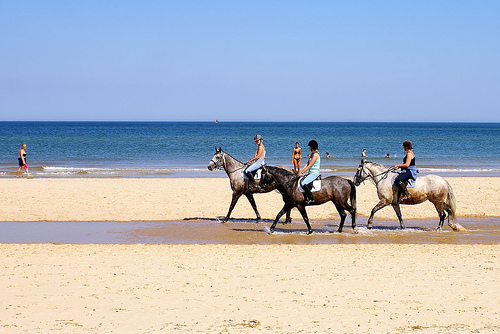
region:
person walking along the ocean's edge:
[16, 141, 29, 178]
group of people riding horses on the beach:
[207, 131, 466, 233]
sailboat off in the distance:
[214, 118, 219, 125]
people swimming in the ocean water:
[322, 148, 392, 158]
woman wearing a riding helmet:
[245, 131, 263, 186]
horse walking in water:
[257, 164, 358, 237]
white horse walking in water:
[351, 155, 462, 235]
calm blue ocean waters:
[55, 121, 186, 166]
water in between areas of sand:
[3, 196, 220, 274]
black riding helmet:
[306, 138, 319, 151]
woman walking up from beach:
[285, 135, 305, 172]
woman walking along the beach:
[4, 131, 44, 185]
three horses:
[214, 128, 497, 246]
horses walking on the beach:
[182, 126, 476, 252]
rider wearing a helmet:
[243, 123, 271, 145]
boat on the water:
[207, 109, 230, 127]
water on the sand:
[5, 197, 498, 267]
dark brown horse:
[257, 163, 370, 236]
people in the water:
[318, 144, 401, 169]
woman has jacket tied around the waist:
[393, 157, 423, 183]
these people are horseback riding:
[163, 90, 484, 252]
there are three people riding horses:
[192, 107, 484, 257]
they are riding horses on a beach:
[175, 124, 473, 249]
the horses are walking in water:
[162, 119, 483, 256]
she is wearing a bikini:
[283, 133, 315, 188]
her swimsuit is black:
[288, 130, 308, 175]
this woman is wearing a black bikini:
[278, 120, 306, 197]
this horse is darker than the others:
[250, 160, 378, 245]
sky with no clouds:
[196, 25, 318, 75]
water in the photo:
[99, 118, 179, 166]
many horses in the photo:
[168, 109, 475, 259]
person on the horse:
[221, 117, 281, 194]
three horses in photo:
[174, 136, 437, 239]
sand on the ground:
[141, 255, 249, 321]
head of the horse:
[182, 139, 237, 189]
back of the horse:
[419, 169, 469, 217]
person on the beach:
[0, 121, 55, 192]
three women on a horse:
[201, 125, 466, 245]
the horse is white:
[350, 155, 460, 231]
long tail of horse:
[443, 179, 461, 225]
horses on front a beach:
[187, 105, 470, 241]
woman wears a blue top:
[296, 135, 328, 203]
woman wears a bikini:
[290, 136, 305, 173]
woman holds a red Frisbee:
[13, 136, 38, 181]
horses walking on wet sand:
[187, 127, 476, 247]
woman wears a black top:
[386, 132, 428, 210]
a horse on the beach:
[223, 144, 273, 206]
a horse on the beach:
[276, 170, 356, 229]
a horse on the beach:
[337, 138, 479, 266]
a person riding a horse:
[398, 148, 419, 200]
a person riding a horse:
[297, 141, 330, 200]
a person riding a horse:
[224, 120, 290, 206]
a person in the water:
[16, 136, 45, 188]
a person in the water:
[288, 128, 306, 183]